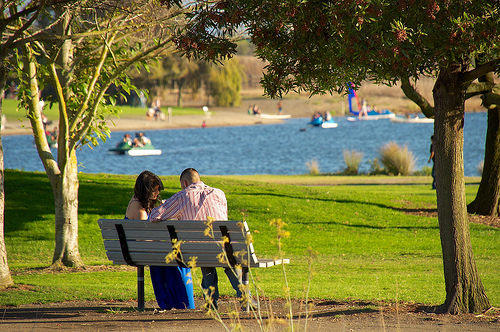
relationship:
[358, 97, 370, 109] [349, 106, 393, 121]
person standing on boat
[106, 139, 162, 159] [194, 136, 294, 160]
boat on water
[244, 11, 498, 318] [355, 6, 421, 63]
tree with flowering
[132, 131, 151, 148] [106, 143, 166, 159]
person on raft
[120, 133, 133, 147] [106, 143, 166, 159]
person on raft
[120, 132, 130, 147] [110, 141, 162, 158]
person in boat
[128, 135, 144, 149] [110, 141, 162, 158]
person in boat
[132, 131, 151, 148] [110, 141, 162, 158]
person in boat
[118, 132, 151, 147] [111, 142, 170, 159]
group in boat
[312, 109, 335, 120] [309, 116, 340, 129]
group in boat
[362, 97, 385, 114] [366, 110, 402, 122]
group in boat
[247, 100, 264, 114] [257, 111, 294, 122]
group in boat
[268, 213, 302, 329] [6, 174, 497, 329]
weed growing from ground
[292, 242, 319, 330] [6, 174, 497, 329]
weed growing from ground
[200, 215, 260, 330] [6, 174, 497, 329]
weed growing from ground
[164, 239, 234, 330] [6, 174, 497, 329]
weed growing from ground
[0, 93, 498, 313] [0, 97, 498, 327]
lawn in park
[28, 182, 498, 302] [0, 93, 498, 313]
sunshine on lawn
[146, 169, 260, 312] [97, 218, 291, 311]
man sitting on bench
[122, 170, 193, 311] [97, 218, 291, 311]
woman sitting on bench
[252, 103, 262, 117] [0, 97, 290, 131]
person on beach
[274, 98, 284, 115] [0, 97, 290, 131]
person on beach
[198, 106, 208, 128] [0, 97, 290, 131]
person on beach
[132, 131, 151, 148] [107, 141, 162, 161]
person sitting on boat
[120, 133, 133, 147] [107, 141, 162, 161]
person sitting on boat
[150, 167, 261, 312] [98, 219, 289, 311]
man sitting on bench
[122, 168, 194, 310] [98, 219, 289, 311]
person sitting on bench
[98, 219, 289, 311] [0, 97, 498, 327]
bench in park